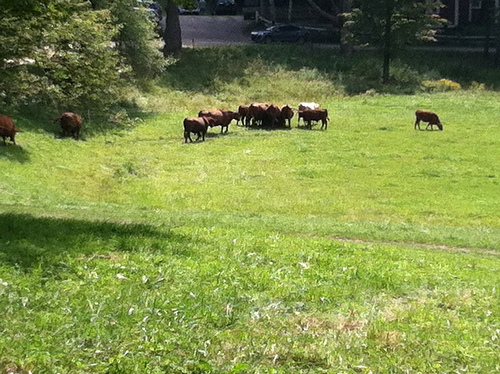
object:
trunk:
[481, 0, 491, 61]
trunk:
[164, 2, 180, 58]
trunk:
[118, 25, 124, 57]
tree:
[114, 2, 125, 57]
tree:
[165, 1, 182, 61]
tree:
[345, 0, 442, 90]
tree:
[480, 0, 495, 52]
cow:
[414, 109, 442, 131]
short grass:
[9, 91, 498, 371]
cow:
[175, 89, 337, 157]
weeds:
[162, 45, 499, 95]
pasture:
[0, 50, 497, 372]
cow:
[198, 109, 240, 133]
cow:
[298, 108, 331, 130]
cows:
[183, 102, 329, 145]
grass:
[127, 163, 376, 205]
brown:
[64, 114, 79, 125]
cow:
[183, 116, 215, 143]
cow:
[0, 115, 23, 146]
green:
[0, 82, 499, 365]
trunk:
[381, 11, 390, 84]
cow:
[56, 112, 83, 140]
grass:
[2, 45, 496, 372]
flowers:
[406, 69, 476, 104]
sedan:
[251, 24, 313, 45]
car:
[250, 24, 310, 45]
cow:
[409, 107, 444, 127]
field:
[2, 0, 499, 371]